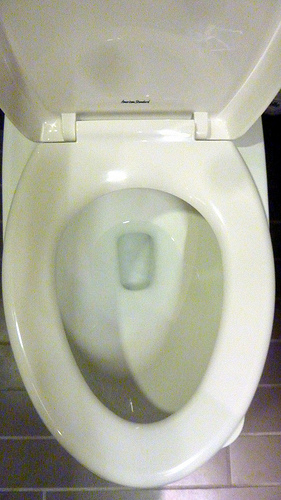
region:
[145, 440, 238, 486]
Light shining off a white toilet seat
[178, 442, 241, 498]
Light reflecting off the floor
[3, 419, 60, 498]
A tile floor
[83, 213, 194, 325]
Clear water in a toilet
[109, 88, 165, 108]
The maker's label on the underside of a toilet seat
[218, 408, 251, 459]
The base of the toilet peaking from under the toilet seat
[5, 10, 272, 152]
A raised toilet lid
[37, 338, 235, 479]
A lowered toilet seat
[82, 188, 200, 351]
Light and shadows in the water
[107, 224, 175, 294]
The drain that empties the toilet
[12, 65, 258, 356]
white toilet with seat down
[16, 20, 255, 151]
white toilet with seat cover up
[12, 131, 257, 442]
clean white toilet with clear water in bowl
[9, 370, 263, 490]
toilet and tile floor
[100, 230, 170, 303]
hole in toilet where water is flushed out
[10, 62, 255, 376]
toilet with lid up and seat down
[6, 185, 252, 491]
white toilet with seat down and tile floor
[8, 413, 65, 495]
neutral colored tile and white grout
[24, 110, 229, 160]
hing where lid and seat can be opened and closed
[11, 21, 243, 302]
white toilet seat, lid, and bowl appear clean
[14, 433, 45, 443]
white line in the tile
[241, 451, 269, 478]
brown tile on the floor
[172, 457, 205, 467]
light reflecting on the toilet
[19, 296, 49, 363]
a white toilet seat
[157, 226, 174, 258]
water inside the toilet bowl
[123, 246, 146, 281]
the drain inside the toilet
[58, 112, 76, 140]
a white connector on the toilet seat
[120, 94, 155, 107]
a company logo on the toilet lid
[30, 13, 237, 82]
the lid of the toilet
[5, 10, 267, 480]
a white toilet in a bathroom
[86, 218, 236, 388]
Water is in the toilet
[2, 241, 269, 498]
The toilet seat is down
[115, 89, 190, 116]
Words are showing on the toilet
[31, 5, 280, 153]
The toilet seat cover is up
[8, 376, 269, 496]
The floor is tiled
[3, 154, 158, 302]
The toilet seat is dirty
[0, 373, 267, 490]
The tiles are rectangular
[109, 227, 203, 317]
A hole is in the toilet bowl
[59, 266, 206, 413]
The toilet bowl has stains inside of it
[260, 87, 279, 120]
An object is to the right of the toilet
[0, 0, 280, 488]
a clean, white toilet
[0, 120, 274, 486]
the seat of the toilet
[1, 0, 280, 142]
the lid of the toilet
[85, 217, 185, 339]
water in the toilet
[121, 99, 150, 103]
logo on the toilet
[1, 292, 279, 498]
dark tiles on the floor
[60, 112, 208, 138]
joint between the lid and the seat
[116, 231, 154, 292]
the hole that the waste goes down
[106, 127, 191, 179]
a shiny reflection on the seat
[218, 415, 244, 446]
an extended part of the toilet